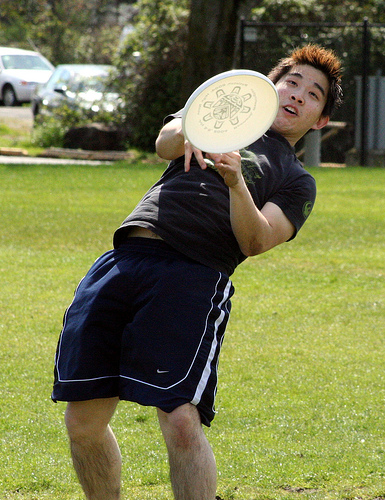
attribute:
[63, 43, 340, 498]
guy — asian, bent, standing, playing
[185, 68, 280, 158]
frisbee — round, white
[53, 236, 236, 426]
shorts — navy blue, blue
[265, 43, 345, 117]
hair — black, auburn, spiked, brown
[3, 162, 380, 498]
grass — green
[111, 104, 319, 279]
tshirt — black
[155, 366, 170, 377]
logo — nike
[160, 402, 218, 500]
leg — hairy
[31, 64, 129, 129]
car — parked, black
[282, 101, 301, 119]
mouth — open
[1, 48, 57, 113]
vehicle — silver, parked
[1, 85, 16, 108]
tire — capped